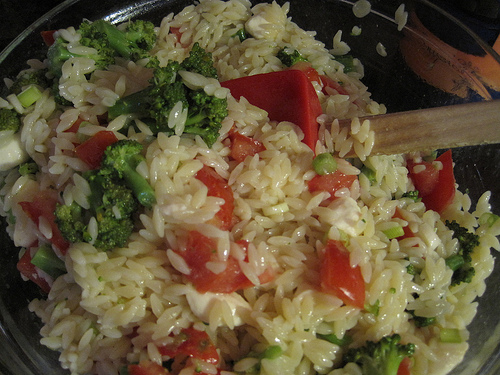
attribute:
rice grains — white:
[253, 167, 300, 234]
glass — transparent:
[394, 44, 416, 92]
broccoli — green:
[78, 19, 158, 67]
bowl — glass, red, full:
[2, 6, 496, 374]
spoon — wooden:
[327, 95, 498, 162]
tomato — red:
[312, 232, 372, 317]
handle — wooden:
[328, 106, 495, 153]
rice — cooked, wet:
[14, 22, 494, 373]